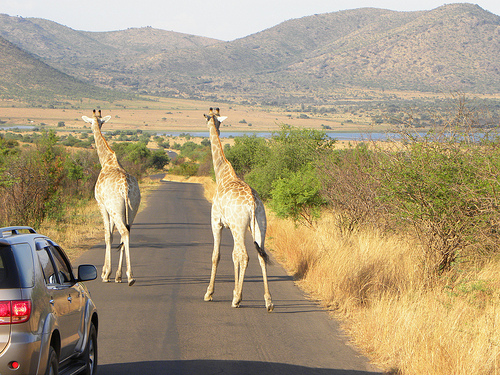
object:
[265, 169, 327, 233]
bush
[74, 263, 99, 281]
mirror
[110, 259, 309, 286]
shadow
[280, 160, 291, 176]
leaf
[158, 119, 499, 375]
grass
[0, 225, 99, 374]
car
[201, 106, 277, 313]
giraffe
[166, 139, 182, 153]
tree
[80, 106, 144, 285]
giraffe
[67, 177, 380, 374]
road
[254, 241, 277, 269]
tuft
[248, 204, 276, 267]
tail